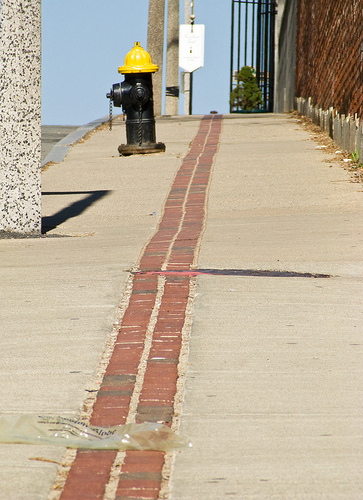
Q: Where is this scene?
A: Street.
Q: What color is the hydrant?
A: Black.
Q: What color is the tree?
A: Green.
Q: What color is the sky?
A: Blue.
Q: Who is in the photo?
A: No one.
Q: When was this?
A: Daytime.